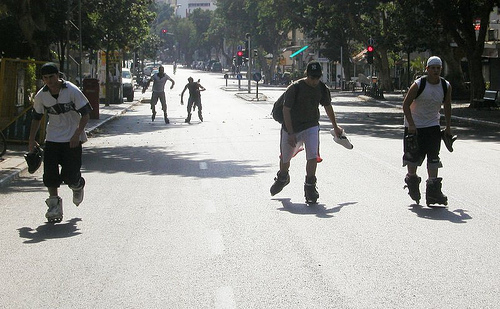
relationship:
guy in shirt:
[269, 61, 354, 210] [281, 80, 335, 132]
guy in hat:
[402, 53, 457, 209] [423, 52, 447, 72]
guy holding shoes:
[269, 61, 354, 210] [327, 126, 355, 151]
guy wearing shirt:
[269, 61, 354, 210] [281, 80, 335, 132]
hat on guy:
[306, 58, 322, 78] [269, 61, 354, 210]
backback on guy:
[272, 78, 290, 128] [269, 61, 354, 210]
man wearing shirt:
[24, 60, 92, 224] [31, 84, 89, 143]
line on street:
[193, 155, 242, 306] [3, 65, 499, 307]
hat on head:
[423, 52, 447, 72] [424, 54, 445, 81]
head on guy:
[424, 54, 445, 81] [402, 53, 457, 209]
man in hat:
[24, 60, 92, 224] [38, 63, 58, 77]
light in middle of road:
[235, 49, 246, 67] [3, 65, 499, 307]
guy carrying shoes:
[269, 61, 354, 210] [327, 126, 355, 151]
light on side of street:
[362, 46, 376, 65] [3, 65, 499, 307]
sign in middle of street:
[252, 72, 263, 96] [3, 65, 499, 307]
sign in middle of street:
[235, 72, 245, 92] [3, 65, 499, 307]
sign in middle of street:
[224, 72, 230, 86] [3, 65, 499, 307]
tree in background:
[389, 0, 498, 106] [1, 2, 496, 124]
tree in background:
[291, 1, 368, 94] [1, 2, 496, 124]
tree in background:
[251, 4, 304, 88] [1, 2, 496, 124]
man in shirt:
[24, 60, 92, 224] [31, 84, 89, 143]